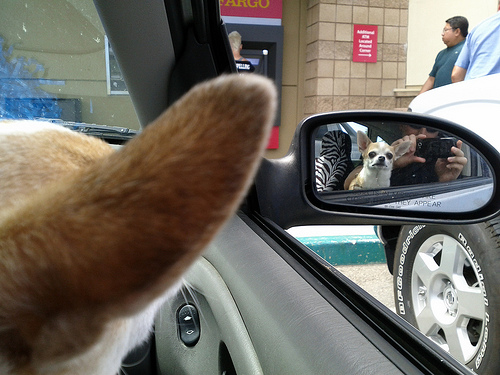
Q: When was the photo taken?
A: Daytime.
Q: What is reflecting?
A: Car side mirror.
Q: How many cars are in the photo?
A: Two.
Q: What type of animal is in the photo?
A: Dog.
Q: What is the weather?
A: Sunny.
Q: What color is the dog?
A: Brown and white.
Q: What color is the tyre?
A: Black.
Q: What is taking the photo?
A: Phone.